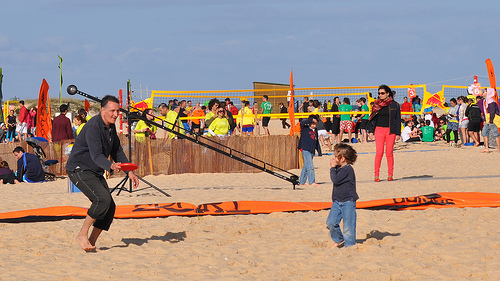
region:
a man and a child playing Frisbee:
[60, 91, 367, 256]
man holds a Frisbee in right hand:
[60, 88, 150, 255]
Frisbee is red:
[109, 154, 143, 186]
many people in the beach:
[0, 71, 498, 250]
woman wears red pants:
[364, 79, 405, 187]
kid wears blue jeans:
[325, 140, 361, 255]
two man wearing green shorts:
[336, 96, 371, 122]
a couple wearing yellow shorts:
[134, 99, 182, 139]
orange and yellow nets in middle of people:
[137, 81, 372, 122]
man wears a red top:
[48, 94, 71, 143]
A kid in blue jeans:
[320, 140, 362, 247]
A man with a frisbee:
[55, 88, 142, 248]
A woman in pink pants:
[366, 82, 412, 184]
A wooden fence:
[186, 139, 289, 169]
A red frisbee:
[112, 156, 137, 181]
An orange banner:
[124, 197, 305, 215]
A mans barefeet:
[67, 213, 120, 264]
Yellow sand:
[177, 227, 337, 272]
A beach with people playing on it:
[10, 57, 480, 270]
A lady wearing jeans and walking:
[292, 108, 324, 188]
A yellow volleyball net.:
[127, 85, 489, 116]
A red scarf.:
[371, 96, 393, 113]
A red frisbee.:
[113, 155, 139, 173]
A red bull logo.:
[421, 90, 448, 111]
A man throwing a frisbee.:
[60, 93, 142, 253]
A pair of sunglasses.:
[374, 90, 391, 97]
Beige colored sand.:
[0, 140, 498, 276]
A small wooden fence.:
[6, 134, 302, 175]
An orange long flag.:
[35, 80, 57, 148]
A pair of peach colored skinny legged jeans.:
[371, 125, 399, 179]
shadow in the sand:
[123, 225, 213, 249]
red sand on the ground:
[197, 231, 273, 263]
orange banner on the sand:
[125, 174, 270, 218]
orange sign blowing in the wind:
[474, 52, 499, 82]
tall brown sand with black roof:
[243, 67, 315, 108]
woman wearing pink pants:
[365, 122, 422, 181]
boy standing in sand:
[312, 134, 359, 246]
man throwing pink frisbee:
[107, 150, 162, 191]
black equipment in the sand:
[72, 73, 312, 178]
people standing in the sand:
[140, 88, 303, 137]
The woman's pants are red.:
[374, 129, 396, 174]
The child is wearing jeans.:
[329, 200, 366, 241]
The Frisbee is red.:
[117, 158, 145, 182]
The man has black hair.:
[99, 92, 119, 107]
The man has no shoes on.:
[74, 232, 114, 259]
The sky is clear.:
[23, 7, 428, 65]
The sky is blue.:
[107, 20, 206, 60]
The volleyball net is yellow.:
[151, 87, 428, 107]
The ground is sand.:
[157, 230, 267, 270]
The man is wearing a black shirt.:
[82, 119, 132, 177]